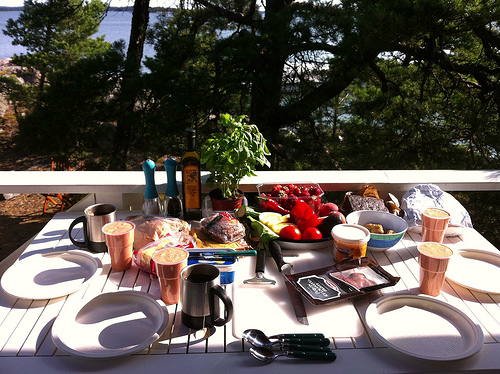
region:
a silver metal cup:
[168, 258, 236, 335]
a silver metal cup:
[178, 264, 236, 335]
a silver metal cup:
[173, 257, 235, 332]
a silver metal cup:
[178, 253, 234, 344]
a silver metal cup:
[188, 262, 223, 335]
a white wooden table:
[168, 334, 223, 372]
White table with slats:
[0, 210, 497, 372]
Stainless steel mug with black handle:
[182, 265, 232, 330]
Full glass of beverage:
[414, 241, 454, 296]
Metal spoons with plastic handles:
[240, 329, 336, 363]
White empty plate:
[364, 291, 484, 363]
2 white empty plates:
[0, 246, 170, 361]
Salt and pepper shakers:
[141, 153, 183, 215]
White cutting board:
[233, 253, 365, 339]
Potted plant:
[202, 111, 272, 210]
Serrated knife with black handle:
[268, 240, 310, 325]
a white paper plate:
[365, 288, 485, 361]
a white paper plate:
[446, 243, 498, 293]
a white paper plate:
[49, 290, 169, 357]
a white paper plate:
[1, 245, 105, 298]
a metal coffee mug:
[180, 262, 232, 330]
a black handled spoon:
[249, 345, 339, 363]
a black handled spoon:
[247, 332, 333, 354]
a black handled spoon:
[240, 325, 323, 340]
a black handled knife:
[267, 239, 310, 324]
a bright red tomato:
[280, 225, 300, 239]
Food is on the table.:
[195, 183, 470, 256]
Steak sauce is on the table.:
[183, 126, 199, 218]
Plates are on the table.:
[365, 294, 480, 361]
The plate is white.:
[400, 315, 453, 349]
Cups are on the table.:
[415, 241, 450, 296]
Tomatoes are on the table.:
[280, 225, 323, 240]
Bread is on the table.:
[140, 217, 171, 236]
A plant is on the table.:
[202, 111, 268, 176]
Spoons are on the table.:
[243, 328, 336, 365]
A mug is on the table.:
[182, 261, 229, 329]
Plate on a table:
[364, 291, 483, 361]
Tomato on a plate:
[280, 223, 300, 239]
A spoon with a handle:
[247, 344, 336, 364]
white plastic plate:
[51, 285, 167, 357]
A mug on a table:
[177, 263, 234, 331]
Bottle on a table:
[182, 124, 202, 214]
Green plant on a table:
[193, 111, 270, 207]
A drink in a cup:
[415, 240, 450, 294]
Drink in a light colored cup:
[415, 205, 447, 241]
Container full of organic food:
[255, 182, 323, 213]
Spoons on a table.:
[241, 324, 343, 366]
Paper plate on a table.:
[46, 289, 173, 363]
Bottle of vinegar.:
[178, 122, 207, 221]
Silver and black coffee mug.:
[173, 258, 239, 333]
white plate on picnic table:
[358, 285, 488, 365]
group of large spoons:
[238, 323, 345, 370]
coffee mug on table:
[178, 257, 236, 333]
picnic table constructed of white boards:
[1, 175, 498, 372]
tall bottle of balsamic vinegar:
[181, 119, 202, 219]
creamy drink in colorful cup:
[153, 244, 193, 305]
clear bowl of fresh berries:
[255, 176, 326, 220]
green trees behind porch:
[0, 5, 498, 250]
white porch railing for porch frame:
[0, 165, 498, 277]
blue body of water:
[1, 0, 498, 160]